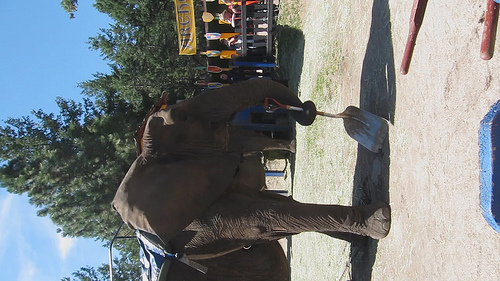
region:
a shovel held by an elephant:
[257, 95, 397, 155]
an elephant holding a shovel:
[95, 87, 397, 279]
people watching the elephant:
[213, 2, 268, 76]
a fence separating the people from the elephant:
[242, 1, 279, 80]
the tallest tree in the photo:
[1, 79, 143, 249]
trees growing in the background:
[58, 1, 205, 96]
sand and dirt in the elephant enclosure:
[401, 130, 471, 244]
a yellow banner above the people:
[176, 0, 194, 68]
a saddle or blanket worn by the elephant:
[131, 220, 189, 279]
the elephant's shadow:
[345, 1, 403, 277]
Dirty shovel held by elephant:
[260, 90, 407, 159]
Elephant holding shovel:
[103, 70, 393, 270]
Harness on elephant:
[100, 223, 271, 268]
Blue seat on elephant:
[128, 233, 180, 279]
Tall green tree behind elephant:
[0, 105, 280, 239]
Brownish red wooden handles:
[397, 3, 499, 82]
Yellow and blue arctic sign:
[165, 0, 202, 57]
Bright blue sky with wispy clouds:
[2, 3, 127, 271]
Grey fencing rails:
[233, 2, 281, 57]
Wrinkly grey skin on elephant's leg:
[197, 190, 402, 250]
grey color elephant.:
[128, 122, 350, 254]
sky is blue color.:
[18, 28, 44, 77]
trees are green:
[43, 143, 122, 196]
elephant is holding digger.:
[246, 83, 428, 161]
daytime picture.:
[19, 23, 476, 250]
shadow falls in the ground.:
[322, 53, 439, 215]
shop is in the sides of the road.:
[159, 15, 336, 93]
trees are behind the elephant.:
[16, 121, 135, 177]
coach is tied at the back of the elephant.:
[91, 242, 166, 277]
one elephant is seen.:
[120, 112, 400, 239]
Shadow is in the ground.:
[340, 30, 425, 265]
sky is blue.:
[15, 30, 60, 70]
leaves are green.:
[21, 136, 97, 172]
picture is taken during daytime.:
[36, 43, 451, 224]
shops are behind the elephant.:
[176, 10, 298, 75]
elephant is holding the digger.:
[262, 81, 388, 151]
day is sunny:
[12, 32, 69, 74]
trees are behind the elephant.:
[6, 18, 149, 279]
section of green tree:
[34, 109, 94, 153]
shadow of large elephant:
[334, 148, 426, 218]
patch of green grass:
[304, 68, 334, 97]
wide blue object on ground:
[460, 119, 498, 223]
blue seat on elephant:
[135, 228, 198, 257]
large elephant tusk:
[262, 89, 320, 119]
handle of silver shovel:
[262, 92, 299, 121]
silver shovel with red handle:
[260, 92, 412, 159]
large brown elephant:
[130, 70, 450, 267]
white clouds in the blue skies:
[13, 223, 84, 263]